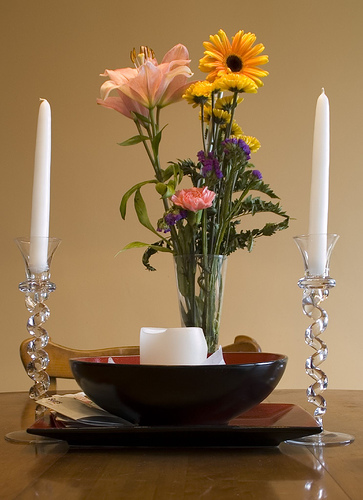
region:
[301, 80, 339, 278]
an unlit white candle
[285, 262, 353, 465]
a glass spiral candle holder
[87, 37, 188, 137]
a pale pink lily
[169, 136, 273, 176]
small purple flowers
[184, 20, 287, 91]
a large yellow daisy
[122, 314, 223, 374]
a thick white candle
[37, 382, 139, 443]
a pile of papers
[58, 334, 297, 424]
a large dark bowl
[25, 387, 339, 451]
a square red plate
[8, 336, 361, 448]
a matching set of dark red dishes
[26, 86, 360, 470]
There are two candles on the table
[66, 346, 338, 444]
The bowl is brown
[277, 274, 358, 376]
The candle holders are glass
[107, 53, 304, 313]
Flowers are in the vase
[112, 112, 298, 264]
The stems are green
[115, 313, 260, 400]
A candle is in the bowl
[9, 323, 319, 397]
One chair is seen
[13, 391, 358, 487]
The bowl is reflecting on the table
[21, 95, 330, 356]
The candles are white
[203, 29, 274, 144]
This is a sunflower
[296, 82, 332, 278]
Tall white pillar candle.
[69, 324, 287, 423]
Candle in black bowl.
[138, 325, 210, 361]
White votive candle.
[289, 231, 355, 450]
Glass taper candle holder.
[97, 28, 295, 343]
Bouquet of flowers.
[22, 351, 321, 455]
Black and red bowl and tray.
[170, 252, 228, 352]
Clear glass flower vase.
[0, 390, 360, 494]
Polished oak wood table top.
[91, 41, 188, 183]
Cut pink orchid flower.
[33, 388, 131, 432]
Stack of letters.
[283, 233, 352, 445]
a glass candle stick is on the table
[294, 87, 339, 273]
a white candle is in the candlestick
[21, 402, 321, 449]
a lacquered tray is on the table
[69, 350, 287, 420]
a lacquered bowl is on top of the tray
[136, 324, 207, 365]
there is a wide white candle in the bowl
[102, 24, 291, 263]
the bouquet is full of colored flowers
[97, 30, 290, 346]
the bouquet is in a vase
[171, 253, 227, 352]
the vase is behind the bowl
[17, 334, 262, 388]
there is a chair behind the table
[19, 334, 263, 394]
the chair is made of wood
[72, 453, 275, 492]
A wood table.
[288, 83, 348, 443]
A candle in a candlestick holder.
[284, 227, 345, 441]
The candlestick holder is made from glass.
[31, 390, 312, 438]
A square plate.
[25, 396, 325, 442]
The plate is red and black.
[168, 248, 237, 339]
A glass vase.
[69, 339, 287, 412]
A black and red bowl.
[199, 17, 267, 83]
A daisy.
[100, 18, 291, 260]
An arrangement of flowers.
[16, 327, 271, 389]
A chair.